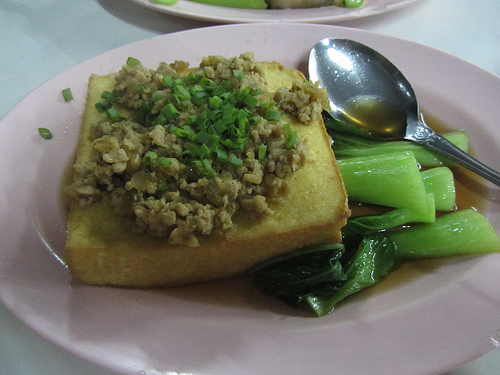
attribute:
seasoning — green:
[148, 84, 273, 187]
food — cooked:
[191, 99, 491, 314]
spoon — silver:
[361, 99, 401, 139]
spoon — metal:
[341, 60, 394, 122]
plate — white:
[31, 155, 488, 375]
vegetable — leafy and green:
[357, 176, 418, 255]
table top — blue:
[13, 52, 43, 84]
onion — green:
[210, 148, 230, 162]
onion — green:
[195, 139, 212, 159]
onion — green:
[262, 108, 281, 121]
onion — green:
[140, 147, 158, 166]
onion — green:
[160, 100, 179, 120]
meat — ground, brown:
[62, 52, 320, 249]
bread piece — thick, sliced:
[60, 58, 353, 288]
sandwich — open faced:
[63, 60, 351, 288]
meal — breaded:
[60, 57, 350, 288]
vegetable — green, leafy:
[245, 207, 484, 317]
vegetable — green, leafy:
[333, 149, 431, 216]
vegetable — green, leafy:
[339, 190, 438, 235]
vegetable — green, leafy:
[423, 163, 456, 213]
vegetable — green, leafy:
[326, 129, 470, 169]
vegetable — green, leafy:
[325, 119, 470, 169]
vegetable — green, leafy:
[320, 110, 374, 137]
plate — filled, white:
[128, 1, 415, 21]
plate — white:
[1, 20, 481, 372]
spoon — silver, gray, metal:
[304, 35, 484, 175]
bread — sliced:
[250, 140, 332, 224]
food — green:
[388, 180, 441, 229]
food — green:
[415, 205, 471, 262]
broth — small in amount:
[337, 94, 407, 143]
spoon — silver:
[306, 36, 498, 186]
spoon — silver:
[275, 40, 469, 173]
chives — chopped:
[164, 72, 250, 169]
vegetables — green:
[349, 139, 448, 274]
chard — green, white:
[330, 135, 473, 313]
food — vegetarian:
[73, 60, 484, 301]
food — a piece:
[82, 58, 287, 245]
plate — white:
[123, 303, 401, 373]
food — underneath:
[78, 65, 457, 303]